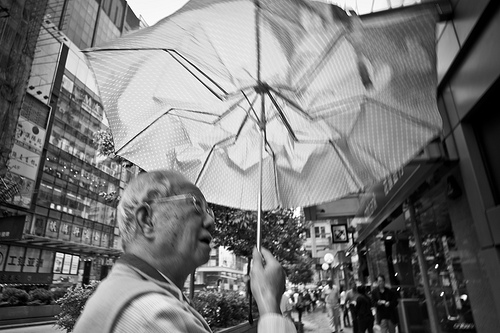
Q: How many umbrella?
A: 1.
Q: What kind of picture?
A: Black and white.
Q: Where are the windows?
A: In the wall of the building.